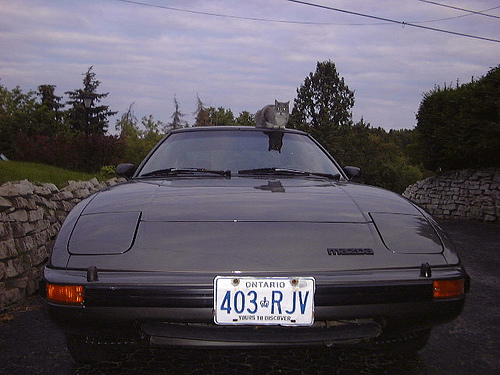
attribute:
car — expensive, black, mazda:
[99, 110, 388, 304]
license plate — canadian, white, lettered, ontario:
[175, 261, 340, 322]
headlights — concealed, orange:
[23, 175, 140, 313]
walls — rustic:
[0, 177, 52, 258]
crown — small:
[284, 269, 318, 292]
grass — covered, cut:
[15, 159, 77, 189]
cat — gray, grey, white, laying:
[253, 96, 320, 130]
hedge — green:
[425, 86, 496, 169]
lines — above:
[350, 9, 497, 58]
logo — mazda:
[305, 215, 446, 288]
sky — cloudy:
[122, 26, 327, 77]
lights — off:
[46, 273, 121, 307]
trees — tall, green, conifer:
[42, 73, 171, 170]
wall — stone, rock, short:
[422, 172, 492, 220]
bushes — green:
[425, 90, 492, 138]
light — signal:
[407, 245, 478, 311]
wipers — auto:
[161, 159, 334, 191]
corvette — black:
[105, 119, 414, 303]